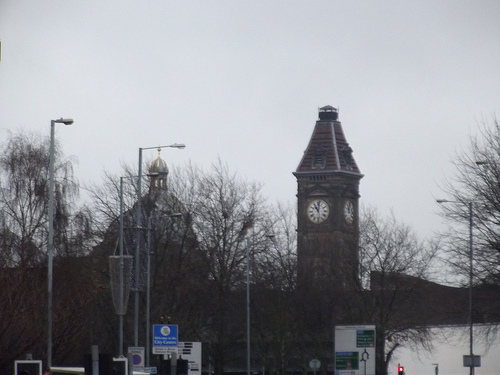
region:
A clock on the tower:
[304, 198, 354, 220]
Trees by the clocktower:
[2, 145, 284, 327]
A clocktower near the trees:
[298, 105, 364, 328]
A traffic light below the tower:
[395, 362, 405, 374]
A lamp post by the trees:
[138, 145, 185, 373]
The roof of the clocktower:
[293, 105, 362, 172]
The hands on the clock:
[312, 195, 324, 211]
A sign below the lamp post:
[149, 322, 179, 374]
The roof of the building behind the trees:
[96, 149, 198, 249]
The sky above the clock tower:
[0, 1, 498, 278]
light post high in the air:
[33, 105, 84, 340]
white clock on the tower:
[300, 190, 333, 225]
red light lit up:
[394, 360, 410, 372]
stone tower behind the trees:
[267, 96, 368, 301]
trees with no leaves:
[2, 128, 105, 345]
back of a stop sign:
[307, 351, 327, 373]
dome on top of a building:
[147, 155, 170, 192]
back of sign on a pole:
[459, 348, 485, 372]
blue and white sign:
[148, 320, 182, 365]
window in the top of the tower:
[310, 143, 330, 170]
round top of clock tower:
[308, 101, 336, 124]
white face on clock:
[308, 196, 340, 223]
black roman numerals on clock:
[308, 199, 340, 223]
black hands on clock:
[308, 198, 335, 229]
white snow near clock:
[398, 311, 473, 374]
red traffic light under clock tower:
[391, 352, 401, 371]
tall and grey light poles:
[98, 148, 188, 329]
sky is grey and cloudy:
[151, 6, 306, 113]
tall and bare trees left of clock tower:
[11, 135, 280, 289]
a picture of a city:
[34, 91, 481, 369]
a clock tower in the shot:
[252, 93, 382, 321]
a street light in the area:
[104, 140, 188, 325]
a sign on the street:
[138, 317, 195, 365]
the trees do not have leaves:
[19, 154, 306, 290]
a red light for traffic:
[387, 350, 415, 374]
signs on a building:
[324, 324, 388, 373]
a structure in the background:
[116, 132, 193, 243]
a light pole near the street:
[428, 183, 483, 374]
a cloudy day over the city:
[55, 31, 457, 214]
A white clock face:
[305, 197, 329, 222]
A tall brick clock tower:
[293, 106, 368, 370]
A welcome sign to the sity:
[152, 325, 178, 353]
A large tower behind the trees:
[150, 151, 170, 193]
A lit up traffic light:
[396, 365, 403, 374]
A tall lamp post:
[47, 117, 75, 373]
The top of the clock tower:
[292, 102, 364, 175]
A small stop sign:
[307, 359, 327, 374]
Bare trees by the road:
[2, 135, 345, 372]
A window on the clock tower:
[309, 148, 328, 169]